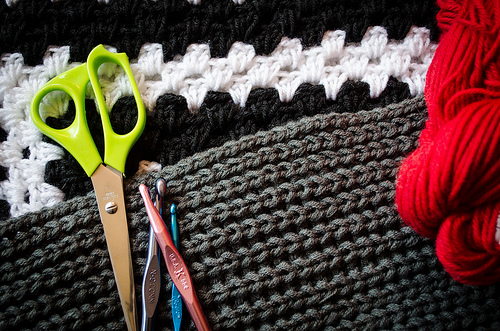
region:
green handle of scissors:
[35, 60, 147, 185]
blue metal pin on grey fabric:
[164, 196, 186, 329]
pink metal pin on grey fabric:
[130, 189, 237, 324]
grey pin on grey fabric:
[127, 168, 174, 319]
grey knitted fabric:
[175, 144, 390, 309]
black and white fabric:
[166, 36, 335, 121]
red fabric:
[403, 24, 480, 241]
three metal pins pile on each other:
[122, 164, 209, 322]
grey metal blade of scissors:
[70, 167, 152, 329]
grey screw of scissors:
[100, 200, 122, 227]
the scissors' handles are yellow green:
[23, 39, 178, 322]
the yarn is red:
[390, 11, 497, 276]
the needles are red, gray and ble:
[143, 154, 208, 306]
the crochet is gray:
[197, 111, 417, 314]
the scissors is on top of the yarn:
[4, 25, 375, 319]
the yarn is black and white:
[133, 76, 235, 139]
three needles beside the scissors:
[123, 170, 238, 327]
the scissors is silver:
[33, 63, 198, 328]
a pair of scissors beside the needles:
[33, 60, 222, 182]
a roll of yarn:
[409, 17, 498, 277]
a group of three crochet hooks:
[135, 175, 215, 326]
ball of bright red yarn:
[391, 0, 497, 287]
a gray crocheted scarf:
[1, 85, 497, 326]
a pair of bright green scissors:
[27, 42, 139, 327]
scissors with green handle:
[28, 41, 138, 327]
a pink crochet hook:
[137, 183, 208, 328]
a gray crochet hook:
[140, 176, 165, 327]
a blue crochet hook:
[167, 201, 183, 327]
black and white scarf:
[0, 0, 496, 222]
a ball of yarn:
[393, 1, 499, 286]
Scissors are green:
[27, 46, 144, 329]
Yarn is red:
[390, 0, 499, 288]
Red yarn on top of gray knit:
[392, 0, 498, 282]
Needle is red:
[138, 187, 206, 329]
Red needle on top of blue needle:
[136, 181, 205, 329]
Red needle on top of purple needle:
[138, 179, 205, 329]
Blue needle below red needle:
[167, 197, 188, 329]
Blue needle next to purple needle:
[168, 195, 183, 328]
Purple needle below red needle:
[142, 170, 168, 329]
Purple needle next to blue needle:
[140, 173, 166, 329]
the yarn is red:
[426, 74, 495, 260]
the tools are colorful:
[139, 187, 199, 324]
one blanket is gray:
[231, 146, 404, 326]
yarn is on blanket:
[405, 2, 497, 286]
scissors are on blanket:
[25, 87, 150, 329]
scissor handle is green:
[28, 56, 143, 165]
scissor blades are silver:
[95, 170, 143, 325]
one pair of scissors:
[32, 67, 154, 327]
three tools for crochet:
[135, 179, 216, 329]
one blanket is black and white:
[31, 31, 398, 106]